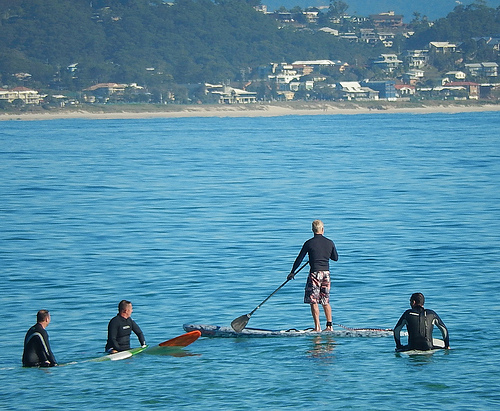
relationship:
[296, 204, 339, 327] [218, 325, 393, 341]
man on surfboard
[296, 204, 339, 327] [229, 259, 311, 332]
man holding oar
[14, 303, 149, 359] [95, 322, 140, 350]
men wearing wetsuit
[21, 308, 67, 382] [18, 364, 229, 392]
man in water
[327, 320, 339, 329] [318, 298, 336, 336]
strap on leg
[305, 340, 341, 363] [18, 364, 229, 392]
reflection in water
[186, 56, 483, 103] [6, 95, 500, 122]
buildings near land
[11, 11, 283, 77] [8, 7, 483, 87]
trees in background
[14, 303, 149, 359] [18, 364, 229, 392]
men in water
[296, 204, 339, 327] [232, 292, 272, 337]
man holding oar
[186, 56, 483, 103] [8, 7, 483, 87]
buildings in background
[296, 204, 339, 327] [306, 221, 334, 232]
man has hair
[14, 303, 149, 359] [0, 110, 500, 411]
men in water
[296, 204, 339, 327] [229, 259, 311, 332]
man with oar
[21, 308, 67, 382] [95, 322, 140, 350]
man in wetsuit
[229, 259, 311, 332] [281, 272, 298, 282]
oar in hand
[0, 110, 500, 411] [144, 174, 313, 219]
water has ripples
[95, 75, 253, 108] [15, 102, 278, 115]
houses on land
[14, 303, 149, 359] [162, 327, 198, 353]
men on surfboard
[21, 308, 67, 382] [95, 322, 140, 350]
man wearing wetsuit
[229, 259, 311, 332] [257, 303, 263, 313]
oar has stripe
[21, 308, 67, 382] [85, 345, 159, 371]
man on surfboard